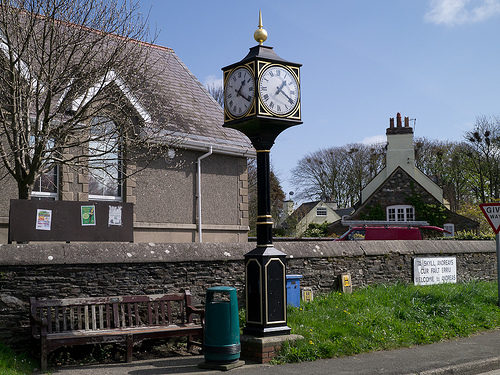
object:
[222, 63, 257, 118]
clock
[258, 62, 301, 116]
face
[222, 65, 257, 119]
face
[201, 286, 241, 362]
trashcan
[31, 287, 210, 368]
bench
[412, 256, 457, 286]
sign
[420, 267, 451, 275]
letters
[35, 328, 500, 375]
sidewalk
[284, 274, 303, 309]
box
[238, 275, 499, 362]
grass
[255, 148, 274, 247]
pole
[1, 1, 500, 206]
sky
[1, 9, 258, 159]
roof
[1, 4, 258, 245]
house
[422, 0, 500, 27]
cloud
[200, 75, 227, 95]
cloud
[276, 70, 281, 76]
roman numeral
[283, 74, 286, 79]
roman numeral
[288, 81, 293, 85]
roman numeral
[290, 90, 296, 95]
roman numeral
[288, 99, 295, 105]
roman numeral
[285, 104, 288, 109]
roman numeral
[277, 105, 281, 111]
roman numeral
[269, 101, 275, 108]
roman numeral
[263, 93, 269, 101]
roman numeral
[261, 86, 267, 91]
roman numeral